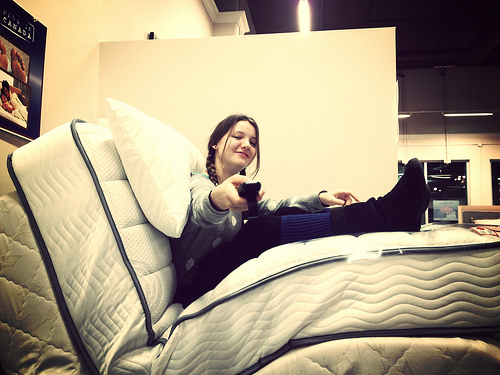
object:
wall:
[98, 27, 397, 208]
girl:
[168, 113, 431, 309]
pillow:
[105, 96, 206, 239]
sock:
[369, 160, 424, 232]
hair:
[206, 112, 260, 184]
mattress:
[6, 119, 500, 375]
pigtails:
[205, 149, 219, 187]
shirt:
[168, 173, 329, 285]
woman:
[171, 114, 431, 309]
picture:
[0, 0, 48, 141]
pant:
[175, 205, 336, 309]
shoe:
[331, 158, 444, 234]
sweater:
[169, 172, 329, 287]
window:
[428, 162, 469, 225]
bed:
[0, 188, 500, 375]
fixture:
[149, 32, 159, 40]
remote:
[252, 184, 256, 187]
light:
[297, 0, 312, 33]